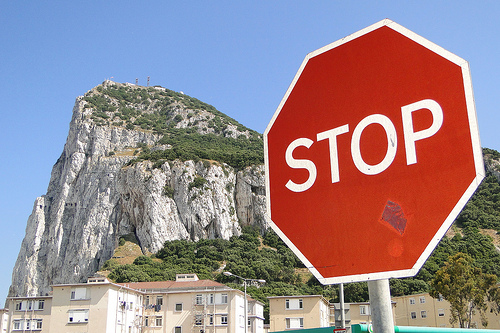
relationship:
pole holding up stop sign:
[298, 203, 440, 331] [200, 42, 481, 277]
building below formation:
[0, 273, 265, 331] [48, 34, 259, 304]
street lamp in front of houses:
[218, 270, 268, 331] [43, 255, 151, 317]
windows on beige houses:
[133, 292, 169, 330] [28, 263, 268, 330]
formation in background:
[62, 86, 240, 293] [25, 18, 484, 264]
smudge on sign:
[380, 198, 417, 259] [247, 17, 489, 290]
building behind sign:
[4, 258, 494, 331] [247, 17, 489, 290]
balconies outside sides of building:
[13, 298, 45, 312] [6, 275, 271, 330]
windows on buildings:
[1, 285, 499, 330] [0, 267, 499, 331]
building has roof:
[0, 268, 265, 330] [110, 265, 234, 297]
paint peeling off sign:
[364, 184, 417, 259] [261, 19, 486, 283]